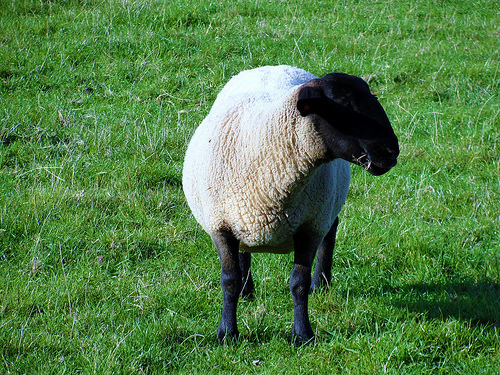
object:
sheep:
[181, 65, 403, 348]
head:
[296, 72, 402, 178]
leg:
[288, 229, 318, 346]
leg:
[310, 216, 341, 293]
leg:
[210, 230, 244, 342]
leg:
[239, 249, 256, 302]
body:
[180, 65, 353, 253]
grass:
[353, 152, 376, 181]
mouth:
[364, 157, 399, 171]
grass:
[0, 0, 497, 373]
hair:
[233, 87, 283, 139]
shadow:
[373, 280, 500, 328]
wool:
[223, 97, 278, 219]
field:
[0, 0, 497, 373]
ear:
[296, 82, 322, 119]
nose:
[384, 142, 402, 159]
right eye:
[341, 99, 352, 109]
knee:
[290, 283, 311, 299]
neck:
[294, 82, 327, 173]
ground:
[0, 0, 497, 375]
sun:
[230, 76, 292, 102]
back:
[329, 160, 351, 224]